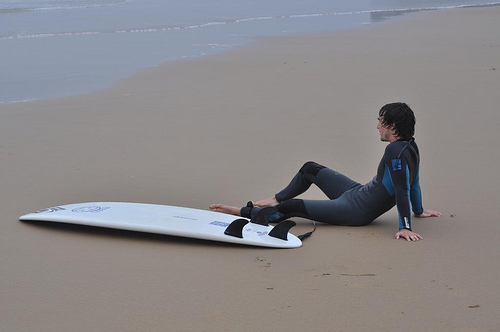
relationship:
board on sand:
[18, 201, 304, 249] [0, 12, 498, 329]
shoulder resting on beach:
[388, 141, 408, 154] [2, 3, 496, 328]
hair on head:
[385, 102, 417, 136] [376, 102, 416, 141]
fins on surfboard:
[268, 218, 295, 239] [30, 197, 301, 292]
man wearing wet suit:
[207, 94, 443, 244] [242, 137, 424, 226]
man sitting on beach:
[207, 94, 443, 244] [2, 3, 496, 328]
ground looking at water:
[320, 246, 500, 331] [3, 2, 485, 107]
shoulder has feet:
[388, 141, 408, 154] [211, 181, 279, 216]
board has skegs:
[18, 201, 304, 249] [223, 204, 297, 241]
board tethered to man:
[18, 201, 304, 249] [207, 94, 443, 244]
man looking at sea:
[207, 94, 443, 244] [2, 0, 499, 112]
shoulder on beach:
[388, 141, 408, 154] [17, 44, 497, 329]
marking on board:
[41, 199, 103, 224] [18, 199, 304, 249]